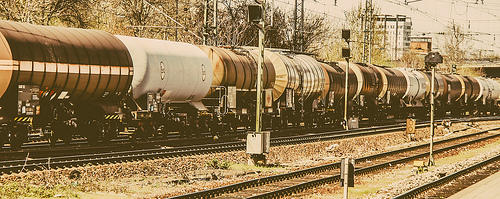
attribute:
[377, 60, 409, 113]
train car — black, cylindrical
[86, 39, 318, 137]
car — cylindrical, black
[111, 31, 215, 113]
tank — white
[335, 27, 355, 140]
electric poll — long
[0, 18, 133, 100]
tank — brown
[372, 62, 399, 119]
train — seventh car, on the tracks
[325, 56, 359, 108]
car — fifth train, on the tracks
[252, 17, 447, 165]
poles — three, in the track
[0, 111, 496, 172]
railway track — long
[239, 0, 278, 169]
signal sign — rail road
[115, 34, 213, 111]
white car — cylindrical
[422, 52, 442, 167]
light poles — three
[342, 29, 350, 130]
light poles — three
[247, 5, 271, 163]
light poles — three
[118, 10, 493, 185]
train — black, cylindrical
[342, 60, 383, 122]
train car — black, cylindrical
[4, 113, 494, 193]
tracks — rusty, metal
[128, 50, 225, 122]
tank — white